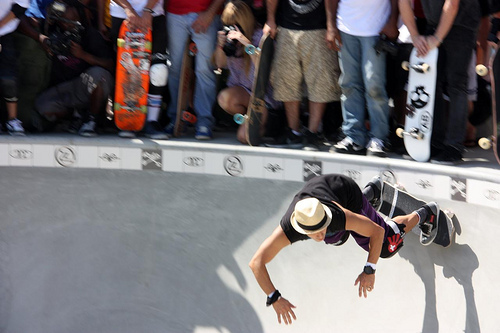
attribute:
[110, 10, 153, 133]
skateboard — white, black, orange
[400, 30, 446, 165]
skateboard — white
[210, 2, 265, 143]
person — taking a picture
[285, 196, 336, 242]
hat — white, cream colored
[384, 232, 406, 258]
logo — red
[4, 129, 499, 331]
rink — gray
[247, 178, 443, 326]
man — skateboarding, riding, bracelets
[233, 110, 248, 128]
wheel — blue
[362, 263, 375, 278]
watch — black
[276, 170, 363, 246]
shirt — black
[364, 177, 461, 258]
skateboard — black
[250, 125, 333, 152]
sneakers — gray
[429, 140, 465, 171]
shoe — black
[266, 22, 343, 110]
shorts — brown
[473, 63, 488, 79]
wheel — white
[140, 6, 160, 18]
band — black